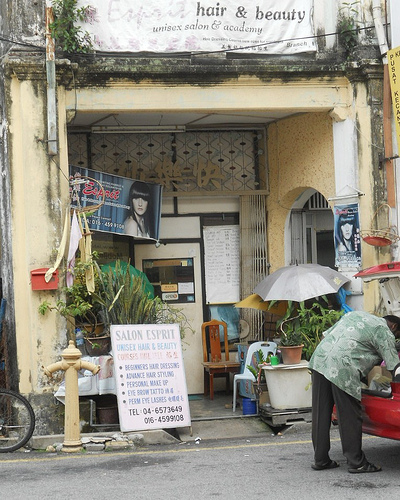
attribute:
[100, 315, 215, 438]
sign — salon har and beauty sign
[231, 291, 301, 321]
umbrella — grey , yellow 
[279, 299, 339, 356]
plant — Green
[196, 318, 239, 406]
chair — old, brown, wooden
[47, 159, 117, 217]
wheel — black 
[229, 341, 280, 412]
patio chair — white plastic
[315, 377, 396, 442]
trunk — red, car trunk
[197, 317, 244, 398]
chair — wooden , brown 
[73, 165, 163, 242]
sign — big 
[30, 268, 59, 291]
receptacle — mail receptacle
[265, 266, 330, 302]
umbrella — gray to silver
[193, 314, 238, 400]
chair — wooden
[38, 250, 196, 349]
plants — green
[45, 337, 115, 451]
hydrant — fire hydrant, painted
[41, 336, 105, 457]
fire hydrant — yellow, tall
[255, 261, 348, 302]
umbrella — gray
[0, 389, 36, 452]
tire — black